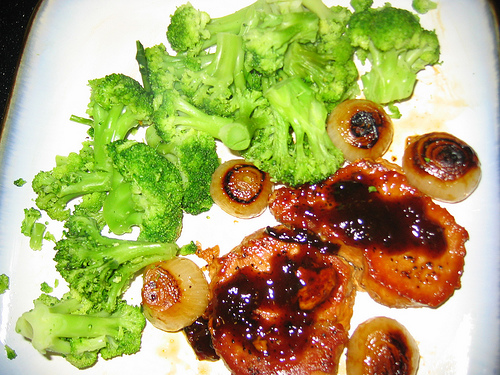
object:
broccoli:
[100, 137, 186, 244]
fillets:
[204, 223, 363, 374]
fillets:
[266, 154, 471, 309]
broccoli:
[343, 3, 440, 103]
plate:
[0, 0, 499, 374]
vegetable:
[240, 78, 342, 186]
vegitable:
[29, 151, 115, 221]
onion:
[400, 131, 482, 204]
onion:
[342, 315, 419, 374]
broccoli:
[20, 205, 43, 239]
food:
[324, 98, 393, 164]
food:
[209, 158, 271, 219]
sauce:
[182, 317, 223, 363]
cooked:
[140, 256, 208, 333]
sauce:
[210, 245, 347, 375]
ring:
[140, 265, 181, 312]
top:
[36, 169, 169, 341]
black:
[263, 224, 341, 255]